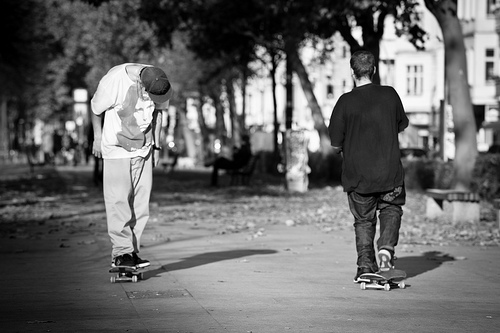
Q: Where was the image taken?
A: It was taken at the park.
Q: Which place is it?
A: It is a park.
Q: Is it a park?
A: Yes, it is a park.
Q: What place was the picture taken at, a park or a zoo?
A: It was taken at a park.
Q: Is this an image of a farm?
A: No, the picture is showing a park.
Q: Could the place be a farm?
A: No, it is a park.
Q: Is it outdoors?
A: Yes, it is outdoors.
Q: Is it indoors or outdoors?
A: It is outdoors.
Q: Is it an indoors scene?
A: No, it is outdoors.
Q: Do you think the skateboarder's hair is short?
A: Yes, the hair is short.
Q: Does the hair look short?
A: Yes, the hair is short.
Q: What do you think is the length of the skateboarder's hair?
A: The hair is short.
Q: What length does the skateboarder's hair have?
A: The hair has short length.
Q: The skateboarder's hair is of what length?
A: The hair is short.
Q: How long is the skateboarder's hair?
A: The hair is short.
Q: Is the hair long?
A: No, the hair is short.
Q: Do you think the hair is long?
A: No, the hair is short.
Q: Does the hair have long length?
A: No, the hair is short.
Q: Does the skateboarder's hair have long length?
A: No, the hair is short.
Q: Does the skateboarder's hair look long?
A: No, the hair is short.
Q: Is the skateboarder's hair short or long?
A: The hair is short.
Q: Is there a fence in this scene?
A: No, there are no fences.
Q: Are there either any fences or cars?
A: No, there are no fences or cars.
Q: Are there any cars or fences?
A: No, there are no fences or cars.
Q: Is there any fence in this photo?
A: No, there are no fences.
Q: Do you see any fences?
A: No, there are no fences.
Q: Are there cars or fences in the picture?
A: No, there are no fences or cars.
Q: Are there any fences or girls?
A: No, there are no fences or girls.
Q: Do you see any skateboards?
A: Yes, there is a skateboard.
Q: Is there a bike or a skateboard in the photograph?
A: Yes, there is a skateboard.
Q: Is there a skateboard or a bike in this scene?
A: Yes, there is a skateboard.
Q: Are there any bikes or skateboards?
A: Yes, there is a skateboard.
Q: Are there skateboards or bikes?
A: Yes, there is a skateboard.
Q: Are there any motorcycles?
A: No, there are no motorcycles.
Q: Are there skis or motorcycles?
A: No, there are no motorcycles or skis.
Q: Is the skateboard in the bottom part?
A: Yes, the skateboard is in the bottom of the image.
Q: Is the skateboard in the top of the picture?
A: No, the skateboard is in the bottom of the image.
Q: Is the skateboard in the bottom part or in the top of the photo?
A: The skateboard is in the bottom of the image.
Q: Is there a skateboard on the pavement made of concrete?
A: Yes, there is a skateboard on the pavement.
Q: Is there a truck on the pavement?
A: No, there is a skateboard on the pavement.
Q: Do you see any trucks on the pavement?
A: No, there is a skateboard on the pavement.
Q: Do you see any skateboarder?
A: Yes, there is a skateboarder.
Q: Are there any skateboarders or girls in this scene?
A: Yes, there is a skateboarder.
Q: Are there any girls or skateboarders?
A: Yes, there is a skateboarder.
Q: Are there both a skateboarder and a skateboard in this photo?
A: Yes, there are both a skateboarder and a skateboard.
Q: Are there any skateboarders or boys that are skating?
A: Yes, the skateboarder is skating.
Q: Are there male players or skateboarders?
A: Yes, there is a male skateboarder.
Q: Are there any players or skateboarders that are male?
A: Yes, the skateboarder is male.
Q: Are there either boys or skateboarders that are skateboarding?
A: Yes, the skateboarder is skateboarding.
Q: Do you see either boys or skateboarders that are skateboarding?
A: Yes, the skateboarder is skateboarding.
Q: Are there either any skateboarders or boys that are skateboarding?
A: Yes, the skateboarder is skateboarding.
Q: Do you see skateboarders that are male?
A: Yes, there is a male skateboarder.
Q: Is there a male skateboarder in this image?
A: Yes, there is a male skateboarder.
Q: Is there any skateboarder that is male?
A: Yes, there is a skateboarder that is male.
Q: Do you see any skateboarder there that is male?
A: Yes, there is a skateboarder that is male.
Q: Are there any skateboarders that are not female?
A: Yes, there is a male skateboarder.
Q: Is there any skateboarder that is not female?
A: Yes, there is a male skateboarder.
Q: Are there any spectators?
A: No, there are no spectators.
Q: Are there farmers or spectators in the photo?
A: No, there are no spectators or farmers.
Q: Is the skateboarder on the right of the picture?
A: Yes, the skateboarder is on the right of the image.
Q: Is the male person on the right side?
A: Yes, the skateboarder is on the right of the image.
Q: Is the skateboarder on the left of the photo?
A: No, the skateboarder is on the right of the image.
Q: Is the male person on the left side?
A: No, the skateboarder is on the right of the image.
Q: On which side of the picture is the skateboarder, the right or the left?
A: The skateboarder is on the right of the image.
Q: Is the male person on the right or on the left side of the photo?
A: The skateboarder is on the right of the image.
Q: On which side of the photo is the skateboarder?
A: The skateboarder is on the right of the image.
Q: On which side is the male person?
A: The skateboarder is on the right of the image.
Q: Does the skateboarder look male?
A: Yes, the skateboarder is male.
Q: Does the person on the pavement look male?
A: Yes, the skateboarder is male.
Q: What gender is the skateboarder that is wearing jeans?
A: The skateboarder is male.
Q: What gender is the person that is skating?
A: The skateboarder is male.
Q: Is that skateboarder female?
A: No, the skateboarder is male.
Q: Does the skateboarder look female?
A: No, the skateboarder is male.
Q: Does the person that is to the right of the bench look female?
A: No, the skateboarder is male.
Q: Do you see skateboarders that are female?
A: No, there is a skateboarder but he is male.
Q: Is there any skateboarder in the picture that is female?
A: No, there is a skateboarder but he is male.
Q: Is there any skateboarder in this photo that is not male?
A: No, there is a skateboarder but he is male.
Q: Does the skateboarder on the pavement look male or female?
A: The skateboarder is male.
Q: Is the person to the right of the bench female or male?
A: The skateboarder is male.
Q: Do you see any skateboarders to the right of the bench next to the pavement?
A: Yes, there is a skateboarder to the right of the bench.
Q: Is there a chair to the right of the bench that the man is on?
A: No, there is a skateboarder to the right of the bench.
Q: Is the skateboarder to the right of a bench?
A: Yes, the skateboarder is to the right of a bench.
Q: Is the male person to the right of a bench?
A: Yes, the skateboarder is to the right of a bench.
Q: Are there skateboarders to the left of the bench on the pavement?
A: Yes, there is a skateboarder to the left of the bench.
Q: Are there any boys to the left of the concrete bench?
A: No, there is a skateboarder to the left of the bench.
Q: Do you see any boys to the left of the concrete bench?
A: No, there is a skateboarder to the left of the bench.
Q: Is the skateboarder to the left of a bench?
A: Yes, the skateboarder is to the left of a bench.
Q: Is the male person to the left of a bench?
A: Yes, the skateboarder is to the left of a bench.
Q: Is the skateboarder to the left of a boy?
A: No, the skateboarder is to the left of a bench.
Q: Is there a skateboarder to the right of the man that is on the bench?
A: Yes, there is a skateboarder to the right of the man.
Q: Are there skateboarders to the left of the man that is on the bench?
A: No, the skateboarder is to the right of the man.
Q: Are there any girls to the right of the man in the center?
A: No, there is a skateboarder to the right of the man.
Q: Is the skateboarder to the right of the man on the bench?
A: Yes, the skateboarder is to the right of the man.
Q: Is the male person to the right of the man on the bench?
A: Yes, the skateboarder is to the right of the man.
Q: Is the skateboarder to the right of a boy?
A: No, the skateboarder is to the right of the man.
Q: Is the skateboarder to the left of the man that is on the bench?
A: No, the skateboarder is to the right of the man.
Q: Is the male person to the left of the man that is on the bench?
A: No, the skateboarder is to the right of the man.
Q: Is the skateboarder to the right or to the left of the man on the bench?
A: The skateboarder is to the right of the man.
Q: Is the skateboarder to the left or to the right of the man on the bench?
A: The skateboarder is to the right of the man.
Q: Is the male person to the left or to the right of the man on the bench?
A: The skateboarder is to the right of the man.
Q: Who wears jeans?
A: The skateboarder wears jeans.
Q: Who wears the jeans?
A: The skateboarder wears jeans.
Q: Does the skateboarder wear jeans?
A: Yes, the skateboarder wears jeans.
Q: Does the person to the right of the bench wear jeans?
A: Yes, the skateboarder wears jeans.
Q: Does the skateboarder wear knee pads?
A: No, the skateboarder wears jeans.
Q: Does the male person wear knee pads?
A: No, the skateboarder wears jeans.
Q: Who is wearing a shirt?
A: The skateboarder is wearing a shirt.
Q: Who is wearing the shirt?
A: The skateboarder is wearing a shirt.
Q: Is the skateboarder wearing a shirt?
A: Yes, the skateboarder is wearing a shirt.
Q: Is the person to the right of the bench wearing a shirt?
A: Yes, the skateboarder is wearing a shirt.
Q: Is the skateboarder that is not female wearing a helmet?
A: No, the skateboarder is wearing a shirt.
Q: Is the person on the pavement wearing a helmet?
A: No, the skateboarder is wearing a shirt.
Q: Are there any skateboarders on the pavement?
A: Yes, there is a skateboarder on the pavement.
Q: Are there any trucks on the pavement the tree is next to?
A: No, there is a skateboarder on the pavement.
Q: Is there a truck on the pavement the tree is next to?
A: No, there is a skateboarder on the pavement.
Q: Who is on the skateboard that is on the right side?
A: The skateboarder is on the skateboard.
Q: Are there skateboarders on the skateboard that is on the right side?
A: Yes, there is a skateboarder on the skateboard.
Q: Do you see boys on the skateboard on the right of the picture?
A: No, there is a skateboarder on the skateboard.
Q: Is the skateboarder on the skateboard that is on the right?
A: Yes, the skateboarder is on the skateboard.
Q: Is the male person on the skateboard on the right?
A: Yes, the skateboarder is on the skateboard.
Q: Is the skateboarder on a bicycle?
A: No, the skateboarder is on the skateboard.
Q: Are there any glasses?
A: No, there are no glasses.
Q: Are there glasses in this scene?
A: No, there are no glasses.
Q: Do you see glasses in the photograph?
A: No, there are no glasses.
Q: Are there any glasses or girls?
A: No, there are no glasses or girls.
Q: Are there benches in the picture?
A: Yes, there is a bench.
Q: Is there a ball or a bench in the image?
A: Yes, there is a bench.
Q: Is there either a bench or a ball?
A: Yes, there is a bench.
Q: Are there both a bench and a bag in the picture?
A: No, there is a bench but no bags.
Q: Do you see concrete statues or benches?
A: Yes, there is a concrete bench.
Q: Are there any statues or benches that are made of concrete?
A: Yes, the bench is made of concrete.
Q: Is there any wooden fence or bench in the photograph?
A: Yes, there is a wood bench.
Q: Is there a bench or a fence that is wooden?
A: Yes, the bench is wooden.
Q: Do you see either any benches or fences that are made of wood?
A: Yes, the bench is made of wood.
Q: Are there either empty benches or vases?
A: Yes, there is an empty bench.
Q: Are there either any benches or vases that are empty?
A: Yes, the bench is empty.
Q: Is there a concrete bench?
A: Yes, there is a bench that is made of concrete.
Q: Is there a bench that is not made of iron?
A: Yes, there is a bench that is made of cement.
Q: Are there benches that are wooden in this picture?
A: Yes, there is a wood bench.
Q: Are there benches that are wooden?
A: Yes, there is a bench that is wooden.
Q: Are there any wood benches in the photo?
A: Yes, there is a bench that is made of wood.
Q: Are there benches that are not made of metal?
A: Yes, there is a bench that is made of wood.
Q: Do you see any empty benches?
A: Yes, there is an empty bench.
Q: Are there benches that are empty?
A: Yes, there is a bench that is empty.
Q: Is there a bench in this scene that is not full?
A: Yes, there is a empty bench.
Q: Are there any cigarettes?
A: No, there are no cigarettes.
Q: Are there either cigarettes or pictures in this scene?
A: No, there are no cigarettes or pictures.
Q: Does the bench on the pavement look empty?
A: Yes, the bench is empty.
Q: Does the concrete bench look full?
A: No, the bench is empty.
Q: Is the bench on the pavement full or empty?
A: The bench is empty.